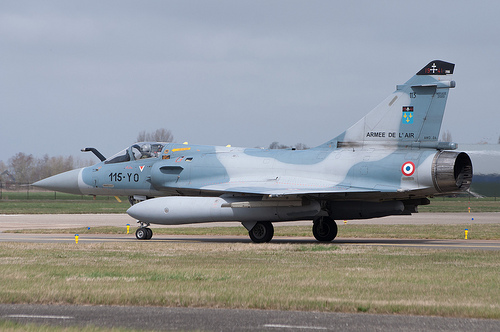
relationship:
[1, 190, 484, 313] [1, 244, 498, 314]
field of grass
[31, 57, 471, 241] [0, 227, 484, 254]
plane sitting on a runway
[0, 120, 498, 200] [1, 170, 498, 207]
trees behind fence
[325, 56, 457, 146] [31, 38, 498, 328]
tail of plane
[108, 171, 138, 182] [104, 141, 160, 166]
115-yo written under cockpit